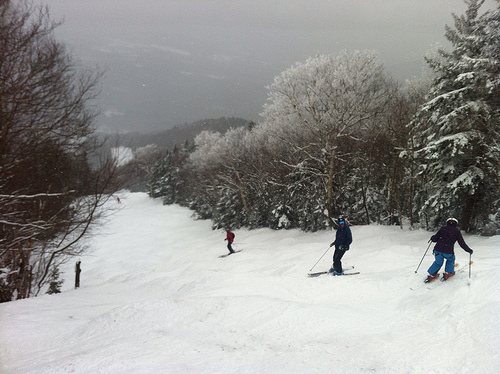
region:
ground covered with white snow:
[142, 297, 295, 364]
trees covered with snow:
[249, 20, 484, 212]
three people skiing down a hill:
[217, 201, 476, 293]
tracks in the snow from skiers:
[52, 298, 153, 363]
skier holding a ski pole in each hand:
[404, 213, 484, 298]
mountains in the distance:
[75, 28, 395, 132]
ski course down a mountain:
[33, 170, 482, 367]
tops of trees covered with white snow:
[180, 50, 405, 161]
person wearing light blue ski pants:
[403, 213, 479, 281]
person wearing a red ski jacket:
[213, 218, 247, 266]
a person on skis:
[410, 215, 475, 285]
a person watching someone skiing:
[311, 213, 357, 278]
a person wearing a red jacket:
[218, 221, 244, 260]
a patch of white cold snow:
[0, 200, 204, 370]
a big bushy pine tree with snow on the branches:
[399, 0, 498, 232]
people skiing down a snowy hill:
[204, 200, 476, 292]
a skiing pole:
[466, 250, 473, 287]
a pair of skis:
[409, 260, 469, 290]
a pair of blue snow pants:
[427, 250, 455, 275]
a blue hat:
[338, 217, 345, 227]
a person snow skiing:
[414, 217, 474, 284]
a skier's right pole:
[465, 248, 474, 280]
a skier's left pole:
[414, 239, 432, 274]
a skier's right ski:
[439, 268, 456, 280]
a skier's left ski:
[425, 272, 439, 282]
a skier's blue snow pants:
[428, 250, 456, 275]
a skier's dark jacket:
[428, 223, 469, 250]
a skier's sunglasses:
[338, 216, 347, 227]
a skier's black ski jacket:
[327, 223, 352, 250]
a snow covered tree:
[410, 0, 497, 235]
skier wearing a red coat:
[211, 224, 249, 258]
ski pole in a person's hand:
[307, 240, 337, 272]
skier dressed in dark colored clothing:
[306, 218, 360, 276]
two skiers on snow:
[211, 213, 364, 277]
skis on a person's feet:
[305, 263, 365, 278]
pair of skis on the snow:
[305, 264, 365, 280]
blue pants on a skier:
[426, 248, 456, 278]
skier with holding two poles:
[407, 213, 479, 290]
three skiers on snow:
[217, 213, 482, 292]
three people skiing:
[196, 213, 482, 291]